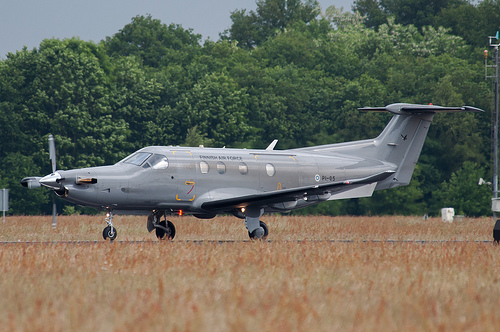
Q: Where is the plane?
A: Runway.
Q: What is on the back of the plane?
A: The tail.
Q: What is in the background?
A: The trees.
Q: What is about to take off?
A: The airplane.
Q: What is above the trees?
A: Dark blue and gray skies.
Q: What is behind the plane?
A: The bushes and trees.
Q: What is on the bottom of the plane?
A: The landing gear.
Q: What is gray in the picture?
A: The airplane.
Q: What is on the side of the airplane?
A: The wing.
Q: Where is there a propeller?
A: Front of plane.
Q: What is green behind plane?
A: Trees.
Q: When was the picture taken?
A: Daytime.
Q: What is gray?
A: Plane.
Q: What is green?
A: Trees.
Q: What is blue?
A: Sky.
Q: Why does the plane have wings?
A: To fly.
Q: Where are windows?
A: On a plane.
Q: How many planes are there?
A: One.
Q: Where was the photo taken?
A: At an airport.